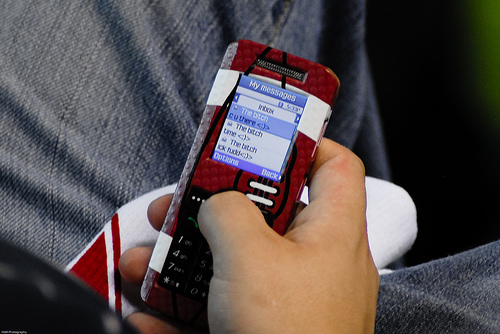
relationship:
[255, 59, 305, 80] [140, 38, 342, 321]
speaker on top of cell phone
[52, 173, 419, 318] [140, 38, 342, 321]
object under cell phone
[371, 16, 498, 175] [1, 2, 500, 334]
space between blue jeans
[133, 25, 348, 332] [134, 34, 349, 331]
cell phone with case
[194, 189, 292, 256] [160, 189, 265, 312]
thumb on keypad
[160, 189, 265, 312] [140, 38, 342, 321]
keypad on cell phone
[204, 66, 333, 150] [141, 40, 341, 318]
white line on phone cover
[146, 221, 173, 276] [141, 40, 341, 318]
white line on phone cover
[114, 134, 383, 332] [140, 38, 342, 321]
hand holding cell phone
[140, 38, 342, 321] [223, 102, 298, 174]
cell phone with messages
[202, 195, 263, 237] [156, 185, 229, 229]
thumb over panel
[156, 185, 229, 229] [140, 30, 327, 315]
panel on device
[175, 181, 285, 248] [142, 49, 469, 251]
fingertips under device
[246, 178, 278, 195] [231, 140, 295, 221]
stripe in border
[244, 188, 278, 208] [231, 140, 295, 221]
stripe in border